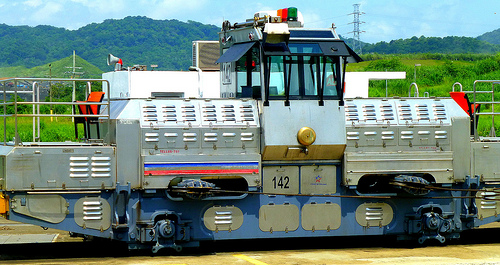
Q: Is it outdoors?
A: Yes, it is outdoors.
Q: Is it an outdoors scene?
A: Yes, it is outdoors.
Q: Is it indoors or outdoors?
A: It is outdoors.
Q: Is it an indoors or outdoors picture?
A: It is outdoors.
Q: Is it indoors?
A: No, it is outdoors.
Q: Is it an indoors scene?
A: No, it is outdoors.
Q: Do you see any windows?
A: Yes, there is a window.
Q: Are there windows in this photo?
A: Yes, there is a window.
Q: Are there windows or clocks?
A: Yes, there is a window.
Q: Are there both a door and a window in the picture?
A: No, there is a window but no doors.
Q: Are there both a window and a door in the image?
A: No, there is a window but no doors.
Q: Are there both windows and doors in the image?
A: No, there is a window but no doors.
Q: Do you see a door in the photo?
A: No, there are no doors.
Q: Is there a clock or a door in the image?
A: No, there are no doors or clocks.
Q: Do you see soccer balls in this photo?
A: No, there are no soccer balls.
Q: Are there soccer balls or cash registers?
A: No, there are no soccer balls or cash registers.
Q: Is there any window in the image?
A: Yes, there is a window.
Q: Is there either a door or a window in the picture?
A: Yes, there is a window.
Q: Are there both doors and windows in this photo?
A: No, there is a window but no doors.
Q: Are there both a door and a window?
A: No, there is a window but no doors.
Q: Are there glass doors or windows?
A: Yes, there is a glass window.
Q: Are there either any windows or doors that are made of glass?
A: Yes, the window is made of glass.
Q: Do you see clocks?
A: No, there are no clocks.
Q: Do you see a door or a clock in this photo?
A: No, there are no clocks or doors.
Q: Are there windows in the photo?
A: Yes, there are windows.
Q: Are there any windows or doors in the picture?
A: Yes, there are windows.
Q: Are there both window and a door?
A: No, there are windows but no doors.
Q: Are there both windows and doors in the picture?
A: No, there are windows but no doors.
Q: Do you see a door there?
A: No, there are no doors.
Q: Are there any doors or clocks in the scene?
A: No, there are no doors or clocks.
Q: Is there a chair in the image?
A: Yes, there is a chair.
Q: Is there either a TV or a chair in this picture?
A: Yes, there is a chair.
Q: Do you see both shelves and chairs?
A: No, there is a chair but no shelves.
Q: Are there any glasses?
A: No, there are no glasses.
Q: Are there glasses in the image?
A: No, there are no glasses.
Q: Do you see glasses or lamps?
A: No, there are no glasses or lamps.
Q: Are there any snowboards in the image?
A: No, there are no snowboards.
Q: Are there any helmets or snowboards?
A: No, there are no snowboards or helmets.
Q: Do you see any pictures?
A: No, there are no pictures.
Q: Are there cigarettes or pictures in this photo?
A: No, there are no pictures or cigarettes.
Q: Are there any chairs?
A: Yes, there is a chair.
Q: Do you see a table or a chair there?
A: Yes, there is a chair.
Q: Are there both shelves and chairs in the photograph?
A: No, there is a chair but no shelves.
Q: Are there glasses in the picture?
A: No, there are no glasses.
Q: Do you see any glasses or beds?
A: No, there are no glasses or beds.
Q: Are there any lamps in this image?
A: No, there are no lamps.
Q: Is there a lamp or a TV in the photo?
A: No, there are no lamps or televisions.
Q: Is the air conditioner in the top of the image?
A: Yes, the air conditioner is in the top of the image.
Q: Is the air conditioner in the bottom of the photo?
A: No, the air conditioner is in the top of the image.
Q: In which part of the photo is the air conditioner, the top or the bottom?
A: The air conditioner is in the top of the image.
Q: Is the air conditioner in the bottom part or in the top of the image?
A: The air conditioner is in the top of the image.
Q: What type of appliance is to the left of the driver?
A: The appliance is an air conditioner.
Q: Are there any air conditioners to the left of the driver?
A: Yes, there is an air conditioner to the left of the driver.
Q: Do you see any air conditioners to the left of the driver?
A: Yes, there is an air conditioner to the left of the driver.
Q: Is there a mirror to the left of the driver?
A: No, there is an air conditioner to the left of the driver.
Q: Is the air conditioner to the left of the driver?
A: Yes, the air conditioner is to the left of the driver.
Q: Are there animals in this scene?
A: No, there are no animals.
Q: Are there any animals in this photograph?
A: No, there are no animals.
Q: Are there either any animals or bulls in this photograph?
A: No, there are no animals or bulls.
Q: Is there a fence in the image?
A: Yes, there is a fence.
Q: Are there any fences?
A: Yes, there is a fence.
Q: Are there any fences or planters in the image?
A: Yes, there is a fence.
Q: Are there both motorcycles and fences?
A: No, there is a fence but no motorcycles.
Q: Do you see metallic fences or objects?
A: Yes, there is a metal fence.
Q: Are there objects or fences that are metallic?
A: Yes, the fence is metallic.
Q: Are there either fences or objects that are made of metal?
A: Yes, the fence is made of metal.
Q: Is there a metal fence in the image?
A: Yes, there is a metal fence.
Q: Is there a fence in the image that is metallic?
A: Yes, there is a fence that is metallic.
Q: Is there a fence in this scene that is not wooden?
A: Yes, there is a metallic fence.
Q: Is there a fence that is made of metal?
A: Yes, there is a fence that is made of metal.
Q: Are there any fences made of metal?
A: Yes, there is a fence that is made of metal.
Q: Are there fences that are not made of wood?
A: Yes, there is a fence that is made of metal.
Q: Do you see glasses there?
A: No, there are no glasses.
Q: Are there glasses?
A: No, there are no glasses.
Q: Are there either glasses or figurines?
A: No, there are no glasses or figurines.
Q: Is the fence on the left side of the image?
A: Yes, the fence is on the left of the image.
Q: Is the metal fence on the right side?
A: No, the fence is on the left of the image.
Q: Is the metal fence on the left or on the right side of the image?
A: The fence is on the left of the image.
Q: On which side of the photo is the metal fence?
A: The fence is on the left of the image.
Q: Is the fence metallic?
A: Yes, the fence is metallic.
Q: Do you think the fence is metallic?
A: Yes, the fence is metallic.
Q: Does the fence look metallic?
A: Yes, the fence is metallic.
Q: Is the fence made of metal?
A: Yes, the fence is made of metal.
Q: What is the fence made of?
A: The fence is made of metal.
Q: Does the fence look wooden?
A: No, the fence is metallic.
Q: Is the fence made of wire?
A: No, the fence is made of metal.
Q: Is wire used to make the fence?
A: No, the fence is made of metal.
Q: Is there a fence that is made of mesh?
A: No, there is a fence but it is made of metal.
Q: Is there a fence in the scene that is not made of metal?
A: No, there is a fence but it is made of metal.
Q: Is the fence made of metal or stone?
A: The fence is made of metal.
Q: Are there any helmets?
A: No, there are no helmets.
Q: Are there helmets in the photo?
A: No, there are no helmets.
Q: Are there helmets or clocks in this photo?
A: No, there are no helmets or clocks.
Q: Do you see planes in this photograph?
A: No, there are no planes.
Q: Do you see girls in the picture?
A: No, there are no girls.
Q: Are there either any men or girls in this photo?
A: No, there are no girls or men.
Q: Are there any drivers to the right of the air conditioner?
A: Yes, there is a driver to the right of the air conditioner.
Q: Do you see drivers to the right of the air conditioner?
A: Yes, there is a driver to the right of the air conditioner.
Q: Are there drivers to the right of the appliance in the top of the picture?
A: Yes, there is a driver to the right of the air conditioner.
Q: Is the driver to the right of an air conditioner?
A: Yes, the driver is to the right of an air conditioner.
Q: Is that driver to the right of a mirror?
A: No, the driver is to the right of an air conditioner.